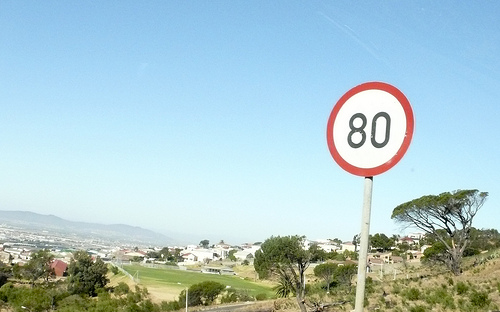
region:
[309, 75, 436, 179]
Red and white sign with "80"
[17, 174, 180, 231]
Mountian tops in the distance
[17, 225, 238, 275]
City line in the distance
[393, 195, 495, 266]
Lovely green trees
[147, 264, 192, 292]
Bright green grass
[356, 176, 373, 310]
Silverish post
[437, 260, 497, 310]
Brown and green landscaping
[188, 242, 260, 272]
Many large white houses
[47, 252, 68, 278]
Dull red bard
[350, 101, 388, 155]
Black numbers on a sign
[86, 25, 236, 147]
this is the sky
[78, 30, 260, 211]
the sky blue in color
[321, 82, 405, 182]
this is a signpost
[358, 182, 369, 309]
this is a post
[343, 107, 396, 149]
this is a writing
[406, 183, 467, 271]
this is a tree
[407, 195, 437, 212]
the leaves are green in color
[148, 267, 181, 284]
this is grass area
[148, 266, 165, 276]
the grass is green in color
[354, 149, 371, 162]
the signpost is white in color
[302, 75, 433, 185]
Round street route sign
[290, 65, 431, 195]
Red, white and black sign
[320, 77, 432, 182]
Sign for route 80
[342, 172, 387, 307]
Metal sign pole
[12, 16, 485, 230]
The sky is clear and blue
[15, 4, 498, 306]
Photo taken during the day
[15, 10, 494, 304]
Nobody shown in the photo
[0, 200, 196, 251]
Hills off in the far distance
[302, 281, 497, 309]
Green shrubs in the field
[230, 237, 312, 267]
Green leaves on the tree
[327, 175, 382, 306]
A pole with a sign on it.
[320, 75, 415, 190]
The sign says the number 80.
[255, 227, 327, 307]
A small tree next to the sign.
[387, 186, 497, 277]
A tree behind the sign.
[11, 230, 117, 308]
Some trees growing together.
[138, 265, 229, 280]
Green grass on a field.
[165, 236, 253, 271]
Buildings in the distance.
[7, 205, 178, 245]
Mountains in the distance.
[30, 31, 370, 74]
The sky is blue.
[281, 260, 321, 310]
The trunk of a tree.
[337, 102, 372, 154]
The number 8 on the sign.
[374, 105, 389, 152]
The number 0 on the sign.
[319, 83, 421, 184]
The red border around the sign.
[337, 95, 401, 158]
The white area of the sign.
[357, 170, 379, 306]
The gray pole that the sign is mounted on.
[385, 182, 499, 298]
The tree on the right.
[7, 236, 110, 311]
The trees on the left.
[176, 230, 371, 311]
The trees in the middle.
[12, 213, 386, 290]
The houses and buildings in the distance.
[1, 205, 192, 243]
The hills/mountains in the distance.